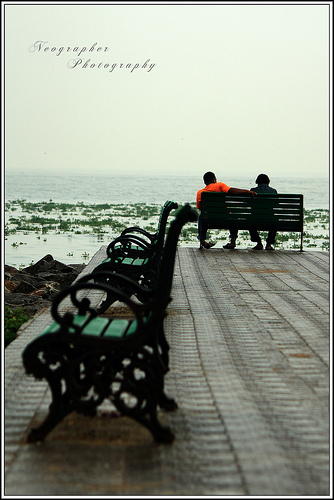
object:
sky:
[190, 8, 329, 133]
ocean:
[6, 174, 185, 198]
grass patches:
[96, 206, 153, 224]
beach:
[15, 198, 93, 255]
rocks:
[19, 265, 45, 308]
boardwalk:
[194, 264, 328, 495]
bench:
[199, 190, 304, 251]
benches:
[91, 197, 181, 314]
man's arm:
[225, 185, 249, 193]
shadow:
[39, 450, 150, 499]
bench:
[20, 198, 200, 448]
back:
[201, 191, 304, 231]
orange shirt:
[196, 181, 232, 209]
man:
[196, 171, 257, 250]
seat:
[22, 311, 143, 355]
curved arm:
[50, 282, 147, 335]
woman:
[250, 173, 281, 251]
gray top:
[249, 192, 278, 195]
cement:
[24, 398, 176, 450]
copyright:
[27, 40, 156, 75]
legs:
[49, 384, 183, 414]